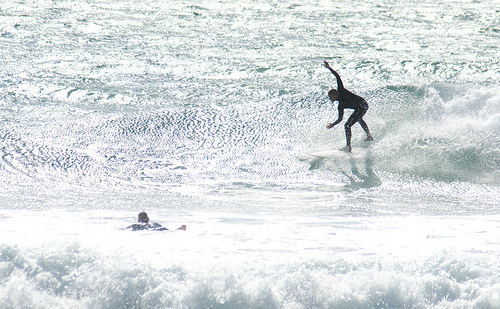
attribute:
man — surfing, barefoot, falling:
[312, 61, 374, 154]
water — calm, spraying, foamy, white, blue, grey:
[1, 2, 490, 210]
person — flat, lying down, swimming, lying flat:
[126, 206, 188, 233]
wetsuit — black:
[342, 87, 368, 137]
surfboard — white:
[315, 143, 368, 163]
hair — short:
[328, 87, 336, 95]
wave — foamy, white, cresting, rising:
[380, 85, 498, 201]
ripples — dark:
[22, 142, 365, 202]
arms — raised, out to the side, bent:
[324, 55, 341, 130]